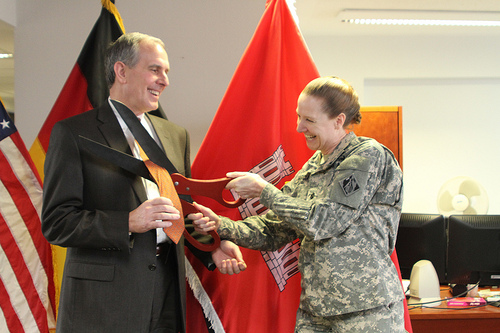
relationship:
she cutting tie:
[252, 55, 435, 330] [128, 118, 197, 276]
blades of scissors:
[78, 101, 163, 178] [91, 101, 261, 258]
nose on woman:
[296, 121, 312, 132] [239, 80, 438, 324]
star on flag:
[1, 113, 11, 133] [0, 96, 41, 328]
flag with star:
[0, 96, 41, 328] [1, 113, 11, 133]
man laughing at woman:
[41, 32, 248, 331] [181, 70, 408, 330]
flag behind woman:
[174, 0, 413, 329] [181, 70, 408, 330]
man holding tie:
[41, 32, 248, 331] [131, 130, 186, 245]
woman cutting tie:
[181, 70, 408, 330] [133, 139, 189, 247]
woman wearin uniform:
[182, 75, 187, 209] [240, 148, 457, 330]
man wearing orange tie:
[41, 32, 248, 331] [107, 110, 187, 250]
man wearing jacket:
[50, 27, 218, 317] [33, 109, 183, 291]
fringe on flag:
[169, 262, 241, 329] [180, 0, 362, 276]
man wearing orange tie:
[41, 32, 248, 331] [137, 139, 185, 245]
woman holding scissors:
[182, 75, 187, 209] [86, 96, 254, 247]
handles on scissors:
[161, 160, 251, 252] [85, 98, 251, 231]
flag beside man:
[0, 99, 58, 332] [49, 38, 209, 325]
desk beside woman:
[401, 262, 495, 330] [249, 80, 420, 330]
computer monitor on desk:
[381, 212, 446, 282] [396, 279, 496, 330]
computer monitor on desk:
[441, 208, 498, 273] [396, 279, 496, 330]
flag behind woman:
[168, 5, 319, 327] [264, 88, 398, 330]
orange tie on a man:
[137, 139, 185, 245] [41, 32, 248, 331]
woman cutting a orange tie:
[181, 70, 408, 330] [137, 139, 185, 245]